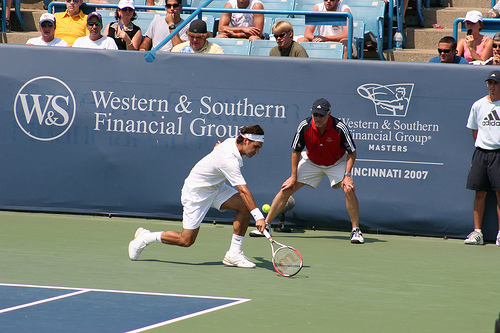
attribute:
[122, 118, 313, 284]
tennis player — tennis 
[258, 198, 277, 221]
tennis ball — tennis 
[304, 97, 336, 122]
cap — black, baseball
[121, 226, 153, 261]
tennis show — white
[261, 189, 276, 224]
ball — green, tennis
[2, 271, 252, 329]
tennis court — blue, white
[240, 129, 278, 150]
headband — white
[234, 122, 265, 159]
sweatband head — white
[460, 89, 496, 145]
addidas t-shirt — adidas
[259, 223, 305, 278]
racket — red, white, black, wilson, tennis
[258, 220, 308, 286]
racket — man's, tennis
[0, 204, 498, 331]
court — tennis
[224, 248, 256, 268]
shoe — white, tennis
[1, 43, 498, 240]
banner advertisement — blue, stadium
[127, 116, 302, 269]
male — tennis player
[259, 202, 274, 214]
tennis ball — yellow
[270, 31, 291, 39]
sunglasses — dark, black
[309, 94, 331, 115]
baseball hat — blue, adidas, basebeall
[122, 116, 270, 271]
man — playing tennis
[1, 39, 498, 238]
banner — blue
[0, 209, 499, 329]
tennis court — blue, white, green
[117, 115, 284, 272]
man — playing tennis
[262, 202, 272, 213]
tennis ball — tennis , yellow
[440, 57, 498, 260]
ball-boy — at tennis match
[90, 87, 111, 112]
letter — large, capital, white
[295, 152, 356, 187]
shorts — white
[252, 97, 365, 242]
linesman — at tennis match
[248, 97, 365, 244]
man — playing tennis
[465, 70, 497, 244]
man — playing tennis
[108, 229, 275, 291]
tennis shoe — white, man's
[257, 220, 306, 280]
racket — red and white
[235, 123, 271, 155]
head — man's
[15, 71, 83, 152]
logo — company